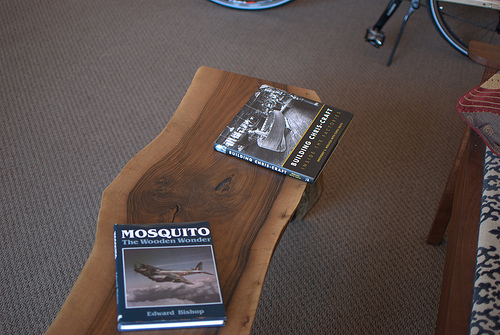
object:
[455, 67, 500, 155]
pillow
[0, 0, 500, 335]
brown carpet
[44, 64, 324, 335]
coffee table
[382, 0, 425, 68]
kick stand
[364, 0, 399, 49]
pedal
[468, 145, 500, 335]
cushion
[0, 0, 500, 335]
room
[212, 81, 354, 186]
book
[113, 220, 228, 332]
book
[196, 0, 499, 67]
bike